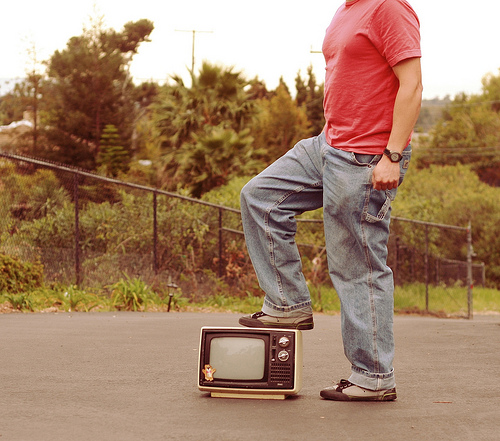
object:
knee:
[240, 181, 277, 211]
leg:
[324, 175, 392, 373]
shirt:
[322, 0, 423, 158]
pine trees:
[18, 18, 160, 198]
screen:
[208, 337, 266, 381]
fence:
[1, 153, 478, 323]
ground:
[0, 318, 499, 439]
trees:
[0, 13, 498, 231]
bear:
[202, 364, 217, 382]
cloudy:
[155, 4, 296, 92]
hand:
[371, 157, 400, 191]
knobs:
[277, 336, 291, 362]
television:
[195, 325, 303, 399]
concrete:
[4, 307, 498, 439]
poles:
[75, 179, 80, 291]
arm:
[379, 1, 422, 140]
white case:
[196, 386, 293, 400]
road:
[6, 313, 316, 438]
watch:
[383, 148, 404, 163]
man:
[241, 0, 426, 402]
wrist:
[381, 150, 403, 164]